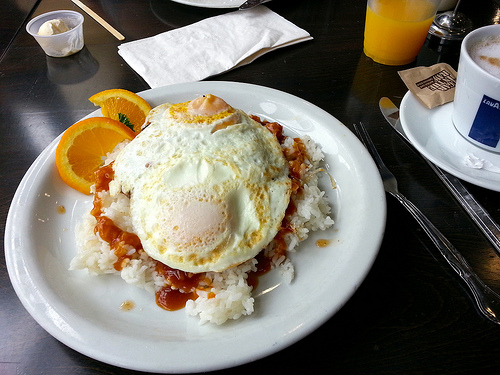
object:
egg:
[105, 92, 293, 273]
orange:
[56, 113, 145, 196]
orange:
[87, 87, 151, 135]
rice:
[64, 115, 337, 324]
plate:
[2, 80, 388, 373]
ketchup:
[153, 285, 198, 312]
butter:
[36, 17, 80, 55]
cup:
[26, 9, 85, 60]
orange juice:
[363, 3, 436, 66]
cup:
[360, 1, 443, 67]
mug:
[451, 25, 500, 153]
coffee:
[469, 33, 499, 81]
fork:
[350, 119, 499, 323]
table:
[0, 0, 498, 374]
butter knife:
[377, 96, 499, 251]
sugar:
[396, 62, 460, 110]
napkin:
[117, 5, 312, 90]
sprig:
[116, 112, 136, 131]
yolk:
[169, 91, 237, 124]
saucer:
[397, 87, 499, 194]